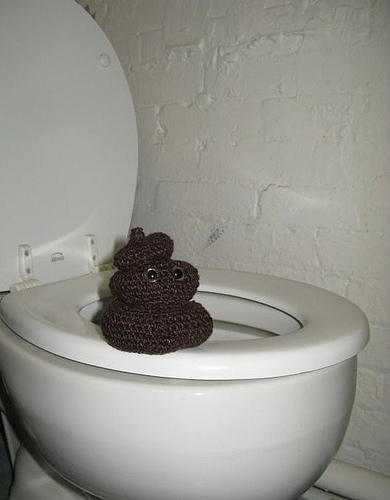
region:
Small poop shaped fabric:
[97, 223, 219, 362]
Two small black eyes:
[137, 253, 188, 293]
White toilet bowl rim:
[8, 252, 371, 385]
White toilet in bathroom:
[2, 245, 365, 499]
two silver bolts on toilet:
[20, 247, 36, 278]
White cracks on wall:
[119, 2, 389, 314]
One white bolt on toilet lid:
[97, 50, 112, 68]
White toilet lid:
[0, 1, 172, 294]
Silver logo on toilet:
[44, 239, 72, 272]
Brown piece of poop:
[105, 218, 211, 356]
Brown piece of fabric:
[98, 223, 223, 373]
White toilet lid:
[2, 252, 372, 399]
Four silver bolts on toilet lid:
[12, 219, 106, 279]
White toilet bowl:
[1, 308, 370, 498]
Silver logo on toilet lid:
[46, 247, 78, 266]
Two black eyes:
[138, 260, 188, 289]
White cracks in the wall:
[103, 10, 373, 272]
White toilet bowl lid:
[4, 244, 381, 412]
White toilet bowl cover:
[0, 1, 153, 294]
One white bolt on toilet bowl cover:
[95, 44, 117, 76]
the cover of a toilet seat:
[18, 46, 115, 274]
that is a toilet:
[31, 260, 371, 495]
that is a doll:
[128, 240, 212, 350]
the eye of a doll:
[145, 266, 166, 295]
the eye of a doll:
[167, 259, 189, 288]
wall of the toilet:
[190, 55, 224, 91]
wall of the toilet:
[213, 226, 254, 258]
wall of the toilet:
[360, 412, 379, 462]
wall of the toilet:
[307, 251, 354, 277]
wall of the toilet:
[148, 16, 195, 98]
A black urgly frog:
[115, 198, 214, 366]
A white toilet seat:
[38, 272, 347, 384]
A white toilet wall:
[357, 424, 388, 487]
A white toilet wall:
[368, 331, 388, 402]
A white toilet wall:
[318, 239, 387, 304]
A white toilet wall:
[202, 215, 290, 269]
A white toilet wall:
[301, 187, 384, 256]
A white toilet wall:
[138, 177, 252, 239]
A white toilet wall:
[135, 13, 250, 98]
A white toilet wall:
[224, 8, 378, 148]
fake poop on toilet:
[102, 220, 207, 350]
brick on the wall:
[302, 179, 374, 218]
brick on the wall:
[253, 101, 325, 143]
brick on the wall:
[195, 119, 260, 158]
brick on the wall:
[199, 74, 258, 107]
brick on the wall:
[344, 430, 383, 467]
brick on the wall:
[179, 38, 262, 88]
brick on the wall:
[159, 7, 229, 40]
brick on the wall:
[184, 1, 230, 24]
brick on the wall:
[183, 185, 246, 215]